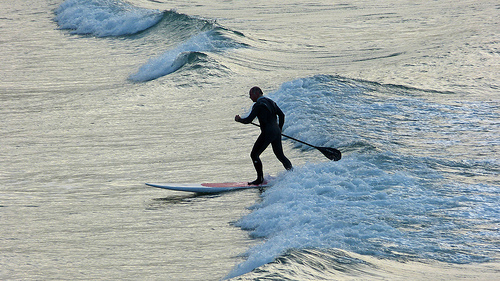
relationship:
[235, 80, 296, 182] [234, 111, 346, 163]
man holding paddle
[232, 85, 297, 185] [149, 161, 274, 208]
man on surfboard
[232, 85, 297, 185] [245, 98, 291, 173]
man wearing wet suit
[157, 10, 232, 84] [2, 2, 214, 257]
waves on ocean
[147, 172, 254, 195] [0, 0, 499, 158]
surfboard on ocean